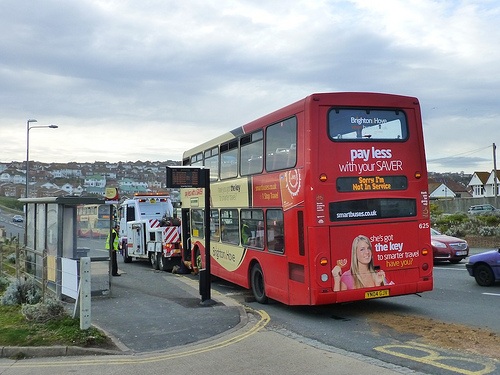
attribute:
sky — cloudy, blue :
[2, 3, 492, 173]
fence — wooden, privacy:
[427, 196, 499, 216]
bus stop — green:
[18, 198, 113, 301]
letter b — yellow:
[371, 344, 496, 374]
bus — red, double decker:
[161, 80, 452, 317]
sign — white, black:
[74, 252, 105, 332]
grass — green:
[1, 240, 112, 354]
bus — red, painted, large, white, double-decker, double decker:
[170, 87, 435, 312]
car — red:
[430, 225, 472, 265]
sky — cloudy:
[210, 27, 441, 68]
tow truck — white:
[112, 187, 181, 276]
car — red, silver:
[419, 180, 499, 302]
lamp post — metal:
[24, 117, 58, 196]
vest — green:
[103, 231, 130, 261]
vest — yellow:
[96, 229, 124, 260]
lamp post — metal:
[16, 110, 65, 208]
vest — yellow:
[103, 228, 118, 248]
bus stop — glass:
[15, 193, 109, 292]